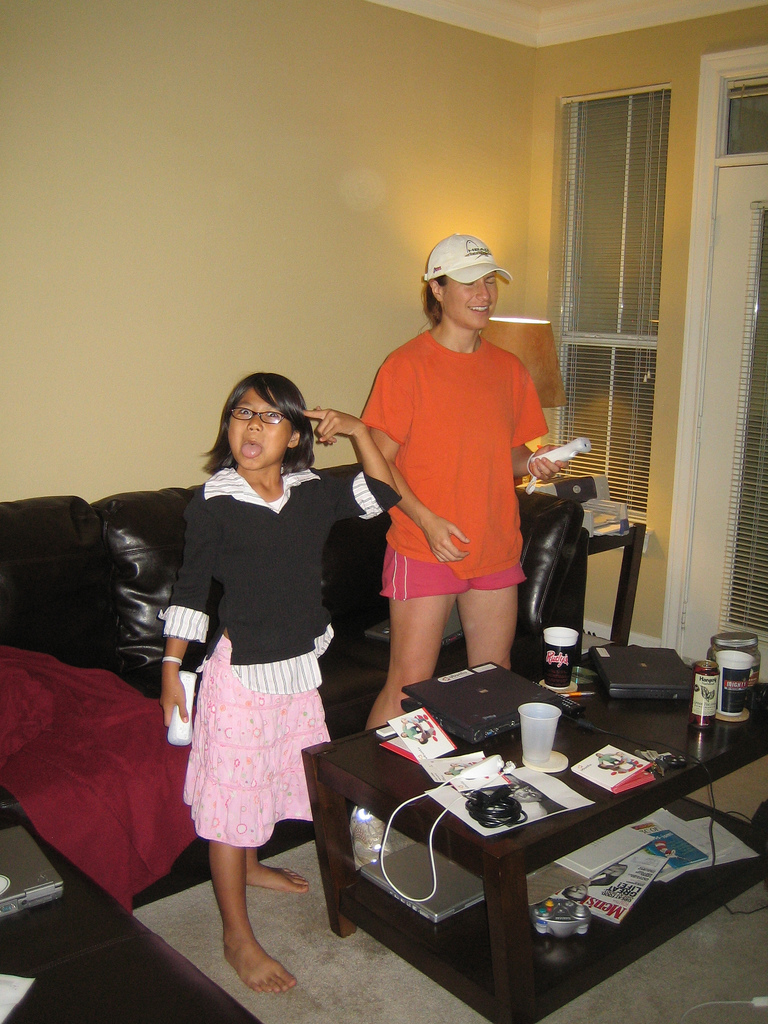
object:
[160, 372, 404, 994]
girl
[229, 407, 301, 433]
glasses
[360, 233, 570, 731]
woman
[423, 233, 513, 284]
hat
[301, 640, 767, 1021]
coffee table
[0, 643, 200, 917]
blanket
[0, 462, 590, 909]
couch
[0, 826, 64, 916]
laptop